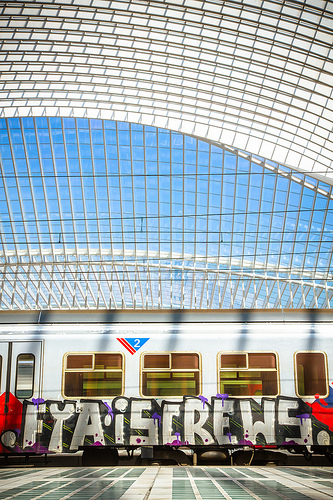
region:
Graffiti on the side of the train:
[17, 393, 313, 450]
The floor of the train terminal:
[24, 463, 278, 492]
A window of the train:
[51, 343, 123, 400]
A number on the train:
[112, 333, 146, 351]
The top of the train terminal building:
[16, 34, 309, 290]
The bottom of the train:
[73, 442, 304, 463]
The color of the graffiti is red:
[1, 390, 24, 451]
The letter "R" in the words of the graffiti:
[180, 394, 213, 448]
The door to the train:
[0, 328, 46, 455]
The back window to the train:
[290, 342, 330, 407]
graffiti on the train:
[97, 392, 206, 446]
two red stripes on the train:
[119, 338, 129, 346]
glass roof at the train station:
[161, 222, 214, 272]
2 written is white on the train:
[131, 336, 138, 346]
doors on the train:
[5, 344, 25, 396]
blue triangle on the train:
[130, 336, 150, 350]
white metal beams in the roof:
[195, 259, 223, 300]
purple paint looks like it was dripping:
[191, 386, 228, 412]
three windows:
[64, 346, 279, 398]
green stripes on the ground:
[177, 462, 267, 496]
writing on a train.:
[8, 395, 317, 458]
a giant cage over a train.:
[0, 7, 332, 311]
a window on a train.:
[48, 335, 140, 401]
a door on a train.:
[0, 335, 53, 456]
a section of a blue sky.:
[148, 147, 155, 159]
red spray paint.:
[299, 377, 327, 424]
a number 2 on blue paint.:
[117, 326, 158, 349]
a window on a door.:
[7, 349, 36, 403]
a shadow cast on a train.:
[152, 307, 198, 351]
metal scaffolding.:
[171, 255, 213, 307]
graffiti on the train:
[1, 382, 329, 458]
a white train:
[0, 322, 332, 457]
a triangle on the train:
[116, 338, 150, 355]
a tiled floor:
[0, 464, 332, 498]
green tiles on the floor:
[0, 467, 325, 499]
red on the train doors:
[0, 389, 24, 437]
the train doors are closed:
[0, 335, 48, 419]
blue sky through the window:
[0, 93, 324, 311]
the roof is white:
[2, 7, 329, 172]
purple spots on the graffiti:
[15, 396, 325, 461]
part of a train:
[135, 400, 155, 416]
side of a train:
[157, 417, 171, 436]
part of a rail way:
[114, 445, 128, 453]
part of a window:
[163, 376, 172, 380]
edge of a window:
[151, 379, 153, 383]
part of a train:
[101, 462, 110, 472]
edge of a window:
[222, 383, 227, 391]